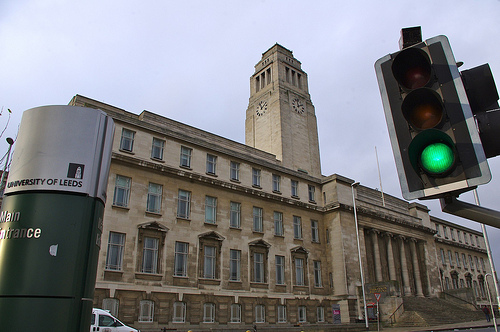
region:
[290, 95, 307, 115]
the clock on the building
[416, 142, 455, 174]
the green traffic light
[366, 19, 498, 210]
the traffic lights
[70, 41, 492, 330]
the big building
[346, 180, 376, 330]
the street light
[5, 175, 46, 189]
the word UNIVERSITY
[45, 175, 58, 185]
the word OF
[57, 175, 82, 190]
the word LEEDS on the sign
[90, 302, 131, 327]
the white vehicle near the building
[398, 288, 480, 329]
the stairs to the building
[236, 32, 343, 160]
Beige tower with large clock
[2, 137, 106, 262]
University of Leeds sign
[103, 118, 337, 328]
Many windows in a beige building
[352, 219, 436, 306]
4 beige pillars in a building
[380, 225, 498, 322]
Stairs leading to pillars in a building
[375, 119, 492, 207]
Lit green street light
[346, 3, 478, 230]
Street light with a green light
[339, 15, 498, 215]
Street light with a camera attached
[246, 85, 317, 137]
2 large clocks with black roman numerals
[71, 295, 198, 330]
White vehicle parked in front of a building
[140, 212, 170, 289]
brown windows in older buidling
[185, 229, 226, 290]
brown windows in older buidling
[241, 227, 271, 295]
brown windows in older buidling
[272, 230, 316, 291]
brown windows in older buidling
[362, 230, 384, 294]
brown windows in older buidling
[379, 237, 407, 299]
brown windows in older buidling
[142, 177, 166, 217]
brown windows in older buidling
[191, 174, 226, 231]
brown windows in older buidling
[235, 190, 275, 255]
brown windows in older buidling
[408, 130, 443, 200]
green signal light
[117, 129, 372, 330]
the facade of a building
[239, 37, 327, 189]
the clock tower at the University of Leeds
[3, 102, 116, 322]
a sign that says Main Entrance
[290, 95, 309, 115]
a clock on the side of a tower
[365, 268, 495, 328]
the stairs in front of a building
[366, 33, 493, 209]
a traffic light with a green signal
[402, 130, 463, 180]
the green signal on a traffic light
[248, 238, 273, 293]
a window on the side of a building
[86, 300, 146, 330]
a white truck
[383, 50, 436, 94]
the red light on a traffic signal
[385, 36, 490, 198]
The stoplight is green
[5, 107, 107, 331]
A large entrance sign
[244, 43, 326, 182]
A clock tower on a building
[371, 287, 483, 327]
Stairs leading up to an entranceway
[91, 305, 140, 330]
The van is white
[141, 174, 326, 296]
The building has two styles of windows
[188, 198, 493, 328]
The building is symmetrical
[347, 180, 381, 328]
A tall white lamppost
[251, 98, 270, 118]
A circular clock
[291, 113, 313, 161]
The tower is made of stone